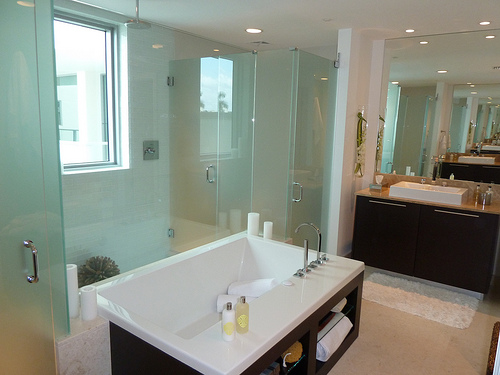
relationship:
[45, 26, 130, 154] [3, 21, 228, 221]
window in wall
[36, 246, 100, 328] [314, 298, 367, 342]
towel inside tub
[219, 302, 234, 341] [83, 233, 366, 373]
bottle on the edge of bathtub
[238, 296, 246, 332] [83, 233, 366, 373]
bottle on the edge of bathtub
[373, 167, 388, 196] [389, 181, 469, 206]
candle on the edge of sink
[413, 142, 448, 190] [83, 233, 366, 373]
faucet for the bathtub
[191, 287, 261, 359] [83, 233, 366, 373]
bottle on bathtub